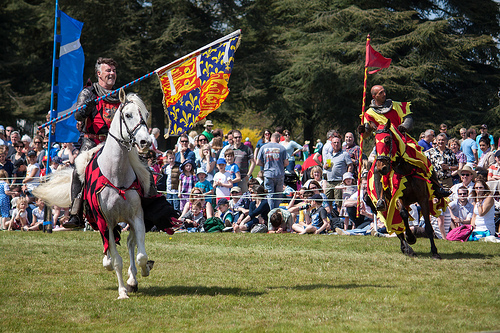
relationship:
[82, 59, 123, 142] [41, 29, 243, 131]
man holding flag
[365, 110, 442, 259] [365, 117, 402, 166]
horse wearing mask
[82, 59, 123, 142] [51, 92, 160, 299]
man riding horse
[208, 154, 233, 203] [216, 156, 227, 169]
girl wearing hat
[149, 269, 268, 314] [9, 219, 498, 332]
shadow on grass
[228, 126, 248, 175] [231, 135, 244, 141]
person wearing sunglasses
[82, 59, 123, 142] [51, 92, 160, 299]
man on horse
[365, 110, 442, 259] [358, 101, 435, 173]
horse wearing costume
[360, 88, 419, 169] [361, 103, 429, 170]
man wearing costume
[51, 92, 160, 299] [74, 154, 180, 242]
horse wearing costume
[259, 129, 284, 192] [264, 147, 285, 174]
man wearing shirt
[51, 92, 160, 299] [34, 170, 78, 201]
horse has tail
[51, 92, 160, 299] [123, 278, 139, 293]
horse has hoof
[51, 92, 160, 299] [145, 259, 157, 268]
horse has hoof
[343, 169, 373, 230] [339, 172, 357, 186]
child wearing hat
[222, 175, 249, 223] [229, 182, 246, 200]
child wearing hat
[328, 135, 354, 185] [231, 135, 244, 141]
person wearing sunglasses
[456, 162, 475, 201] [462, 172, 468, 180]
person wearing sunglasses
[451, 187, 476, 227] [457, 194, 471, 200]
person wearing sunglasses